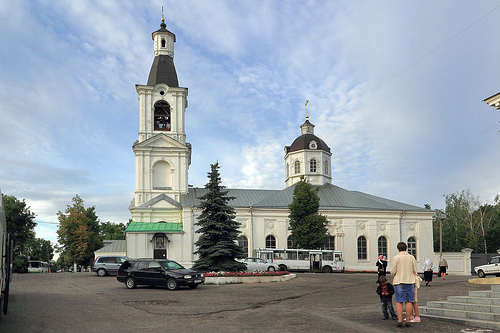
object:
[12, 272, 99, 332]
street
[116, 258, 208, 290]
car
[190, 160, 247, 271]
tree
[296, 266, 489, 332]
driveway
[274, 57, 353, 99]
clouds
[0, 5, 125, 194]
sky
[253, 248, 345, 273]
bus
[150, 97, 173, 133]
window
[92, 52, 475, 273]
church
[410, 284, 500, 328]
steps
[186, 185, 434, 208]
roof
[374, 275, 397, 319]
boy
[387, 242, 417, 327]
woman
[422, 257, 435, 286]
people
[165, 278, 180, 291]
tire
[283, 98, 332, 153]
steeple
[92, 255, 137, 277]
van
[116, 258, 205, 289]
station wagon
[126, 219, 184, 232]
awning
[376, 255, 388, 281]
man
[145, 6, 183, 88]
tower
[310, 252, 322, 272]
door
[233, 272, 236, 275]
flowers